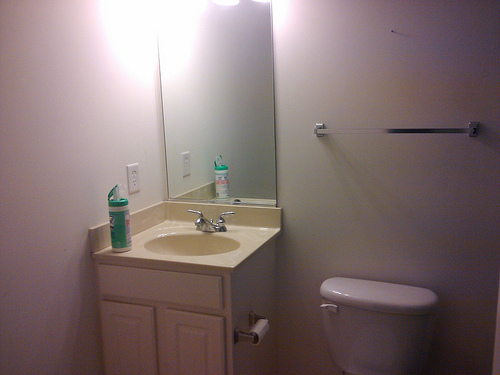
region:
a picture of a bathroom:
[56, 98, 497, 364]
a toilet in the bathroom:
[311, 278, 457, 369]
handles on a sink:
[180, 202, 245, 233]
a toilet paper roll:
[228, 302, 280, 348]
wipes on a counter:
[98, 186, 142, 261]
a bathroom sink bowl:
[143, 232, 249, 272]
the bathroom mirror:
[137, 13, 282, 223]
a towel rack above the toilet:
[291, 101, 497, 173]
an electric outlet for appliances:
[121, 158, 146, 205]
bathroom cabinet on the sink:
[95, 285, 237, 371]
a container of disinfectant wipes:
[107, 182, 132, 252]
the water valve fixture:
[185, 205, 230, 230]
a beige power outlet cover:
[125, 160, 140, 191]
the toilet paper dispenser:
[235, 310, 270, 346]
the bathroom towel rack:
[313, 118, 483, 140]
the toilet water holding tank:
[318, 274, 440, 374]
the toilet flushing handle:
[320, 301, 340, 313]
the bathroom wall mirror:
[155, 3, 277, 207]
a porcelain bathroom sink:
[133, 220, 279, 268]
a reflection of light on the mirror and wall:
[96, 0, 216, 82]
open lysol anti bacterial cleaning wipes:
[85, 175, 146, 265]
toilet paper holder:
[245, 312, 275, 348]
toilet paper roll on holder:
[250, 305, 273, 340]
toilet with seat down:
[301, 268, 456, 354]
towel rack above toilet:
[305, 88, 488, 163]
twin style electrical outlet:
[112, 157, 150, 198]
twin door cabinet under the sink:
[75, 260, 285, 371]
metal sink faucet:
[178, 205, 248, 235]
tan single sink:
[95, 190, 291, 265]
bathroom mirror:
[128, 0, 301, 207]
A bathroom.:
[4, 2, 497, 373]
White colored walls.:
[2, 1, 496, 371]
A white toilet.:
[316, 270, 435, 373]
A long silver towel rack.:
[312, 119, 482, 139]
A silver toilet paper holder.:
[238, 309, 273, 347]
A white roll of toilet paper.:
[251, 319, 270, 343]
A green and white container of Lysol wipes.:
[105, 185, 135, 255]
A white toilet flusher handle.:
[320, 301, 339, 316]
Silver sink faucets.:
[182, 203, 233, 235]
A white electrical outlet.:
[124, 163, 146, 198]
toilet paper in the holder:
[221, 309, 282, 348]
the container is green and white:
[98, 183, 160, 275]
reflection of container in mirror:
[203, 144, 238, 205]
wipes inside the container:
[109, 171, 122, 205]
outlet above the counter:
[113, 153, 155, 204]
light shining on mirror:
[100, 7, 259, 69]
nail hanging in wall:
[379, 20, 404, 45]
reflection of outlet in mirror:
[172, 140, 197, 188]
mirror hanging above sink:
[155, 3, 285, 208]